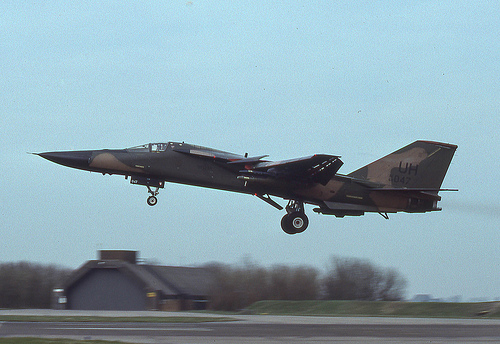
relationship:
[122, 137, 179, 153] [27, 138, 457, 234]
pilothouse on jetplane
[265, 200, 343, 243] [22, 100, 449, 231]
wheel of jetplane